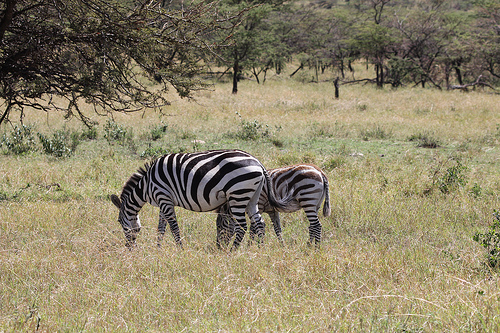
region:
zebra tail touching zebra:
[260, 165, 295, 208]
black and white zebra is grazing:
[109, 149, 265, 251]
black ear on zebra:
[108, 193, 123, 208]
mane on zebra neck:
[118, 156, 163, 204]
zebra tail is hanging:
[320, 169, 332, 219]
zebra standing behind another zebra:
[263, 164, 330, 253]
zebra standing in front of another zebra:
[107, 149, 267, 253]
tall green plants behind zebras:
[36, 126, 81, 158]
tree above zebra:
[2, 0, 253, 128]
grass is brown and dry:
[3, 200, 495, 331]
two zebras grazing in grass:
[89, 121, 356, 274]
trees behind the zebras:
[4, 1, 499, 61]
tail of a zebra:
[320, 169, 337, 225]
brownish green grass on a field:
[9, 259, 488, 330]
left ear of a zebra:
[102, 190, 123, 210]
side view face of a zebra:
[114, 205, 149, 257]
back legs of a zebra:
[219, 202, 269, 266]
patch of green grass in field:
[307, 137, 340, 150]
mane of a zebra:
[115, 158, 162, 205]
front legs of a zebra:
[152, 208, 186, 260]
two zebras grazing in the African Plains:
[1, 1, 498, 332]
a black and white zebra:
[111, 148, 267, 249]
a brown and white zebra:
[263, 162, 331, 246]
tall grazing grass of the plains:
[0, 242, 499, 332]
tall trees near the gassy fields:
[1, 1, 499, 123]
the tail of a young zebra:
[322, 171, 332, 218]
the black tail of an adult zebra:
[261, 166, 294, 214]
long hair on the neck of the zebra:
[119, 150, 154, 206]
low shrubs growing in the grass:
[1, 118, 498, 154]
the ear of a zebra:
[108, 193, 121, 209]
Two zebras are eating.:
[75, 132, 375, 283]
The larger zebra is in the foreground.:
[102, 140, 280, 262]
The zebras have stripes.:
[70, 131, 357, 256]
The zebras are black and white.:
[88, 137, 369, 264]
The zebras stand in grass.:
[0, 127, 492, 317]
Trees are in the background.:
[0, 0, 495, 135]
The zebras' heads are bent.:
[105, 135, 272, 260]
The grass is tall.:
[0, 211, 497, 328]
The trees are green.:
[131, 2, 496, 108]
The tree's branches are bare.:
[0, 58, 177, 135]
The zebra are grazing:
[108, 148, 331, 254]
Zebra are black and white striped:
[111, 148, 330, 258]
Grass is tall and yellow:
[1, 76, 499, 332]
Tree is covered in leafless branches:
[0, 0, 244, 122]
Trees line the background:
[1, 0, 498, 95]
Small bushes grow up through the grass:
[1, 123, 478, 211]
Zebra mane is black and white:
[108, 145, 193, 202]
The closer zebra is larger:
[108, 153, 335, 269]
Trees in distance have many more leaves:
[221, 5, 498, 73]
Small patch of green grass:
[189, 135, 497, 167]